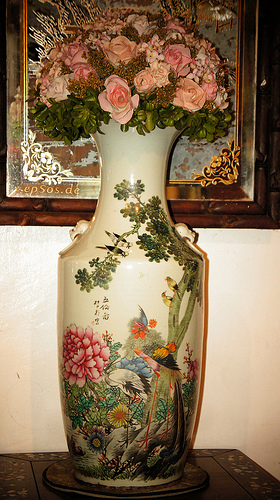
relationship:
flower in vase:
[92, 73, 148, 126] [35, 90, 228, 470]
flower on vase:
[96, 73, 140, 126] [62, 140, 218, 480]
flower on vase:
[106, 403, 132, 426] [57, 114, 206, 488]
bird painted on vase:
[92, 355, 155, 416] [57, 114, 206, 488]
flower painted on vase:
[59, 319, 109, 387] [46, 106, 231, 485]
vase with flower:
[57, 118, 211, 491] [34, 28, 266, 154]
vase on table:
[57, 114, 206, 488] [2, 448, 278, 498]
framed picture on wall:
[4, 3, 100, 221] [218, 388, 264, 424]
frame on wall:
[6, 0, 264, 218] [8, 201, 53, 230]